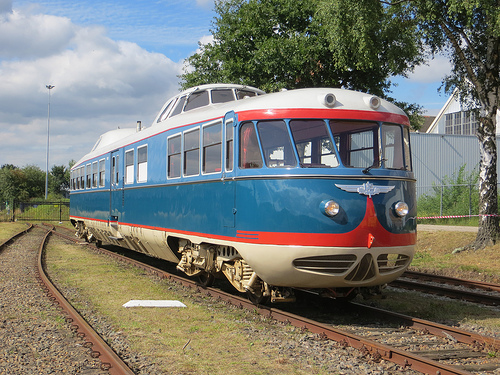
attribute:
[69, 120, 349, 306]
train — vintage, red, blue, white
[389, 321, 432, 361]
track — occupied, empty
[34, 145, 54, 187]
post — tall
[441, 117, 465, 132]
windows — small, passenger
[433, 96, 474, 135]
house — white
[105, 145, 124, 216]
door — blue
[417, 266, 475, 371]
tracks — set, rusty, brown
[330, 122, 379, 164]
windshield — large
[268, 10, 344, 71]
tree — green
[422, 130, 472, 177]
fence — white, metal, small, large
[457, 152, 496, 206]
tree bark — speckled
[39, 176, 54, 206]
pole — tall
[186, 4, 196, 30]
sky — cloudy